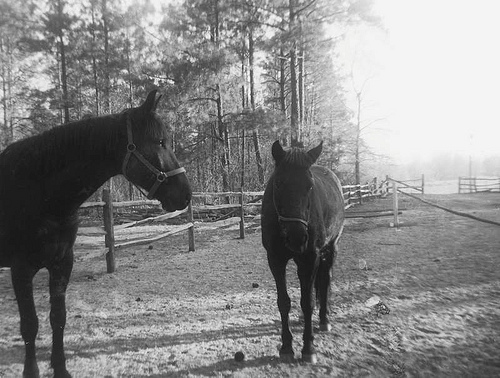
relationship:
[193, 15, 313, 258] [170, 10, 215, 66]
trees with few leaves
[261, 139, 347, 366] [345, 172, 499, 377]
horse in a pen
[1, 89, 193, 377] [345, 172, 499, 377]
horse in a horse pen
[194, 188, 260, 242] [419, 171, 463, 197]
fence has a gate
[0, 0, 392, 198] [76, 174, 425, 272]
trees line fence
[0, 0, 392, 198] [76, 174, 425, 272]
trees bordering fence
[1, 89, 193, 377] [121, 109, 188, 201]
horse has a bridle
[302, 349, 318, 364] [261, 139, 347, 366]
hoof of horse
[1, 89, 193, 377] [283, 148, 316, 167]
horse has a forelock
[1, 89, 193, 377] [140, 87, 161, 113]
horse has a black ear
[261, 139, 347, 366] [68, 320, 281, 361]
horse has a shadow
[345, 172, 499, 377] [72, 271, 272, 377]
horse pen has a dirt ground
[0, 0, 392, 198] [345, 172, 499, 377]
trees bordering horse pen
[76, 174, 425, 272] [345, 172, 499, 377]
fence around horse pen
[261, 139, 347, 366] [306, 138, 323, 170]
horse has black ears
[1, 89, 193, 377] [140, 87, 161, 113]
horse has black ears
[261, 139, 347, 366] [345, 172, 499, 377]
horse on farm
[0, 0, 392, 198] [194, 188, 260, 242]
trees border fence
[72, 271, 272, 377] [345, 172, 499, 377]
dirt ground in pen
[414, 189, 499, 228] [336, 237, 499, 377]
log in dirt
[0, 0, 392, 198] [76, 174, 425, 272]
trees along fence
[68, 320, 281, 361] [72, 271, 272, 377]
shadows from sunlight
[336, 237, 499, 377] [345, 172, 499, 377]
dirt in pen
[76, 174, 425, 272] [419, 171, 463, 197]
fence has a gate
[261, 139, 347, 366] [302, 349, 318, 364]
horse has grey hooves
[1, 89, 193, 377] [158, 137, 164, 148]
horse has dark eyes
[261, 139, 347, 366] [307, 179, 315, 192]
horse has dark eyes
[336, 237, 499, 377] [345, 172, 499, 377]
dirt in horse pen